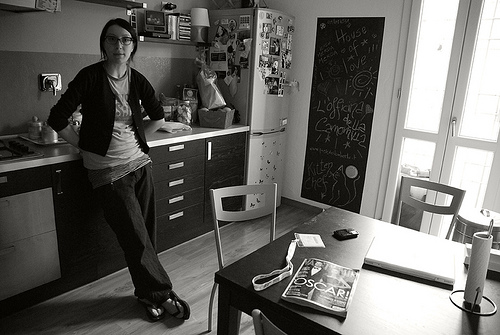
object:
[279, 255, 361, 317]
magazine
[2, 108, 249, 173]
drawer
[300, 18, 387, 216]
chalkboard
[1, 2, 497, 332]
kitchen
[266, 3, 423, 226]
wall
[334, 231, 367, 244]
cell phone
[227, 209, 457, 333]
table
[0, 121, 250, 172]
counter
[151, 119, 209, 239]
counter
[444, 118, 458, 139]
handle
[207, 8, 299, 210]
refrigerators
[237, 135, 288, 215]
freezer section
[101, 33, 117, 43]
glasses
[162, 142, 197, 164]
drawer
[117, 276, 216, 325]
flip flops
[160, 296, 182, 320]
woman's foot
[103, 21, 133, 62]
face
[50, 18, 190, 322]
woman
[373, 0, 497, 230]
door